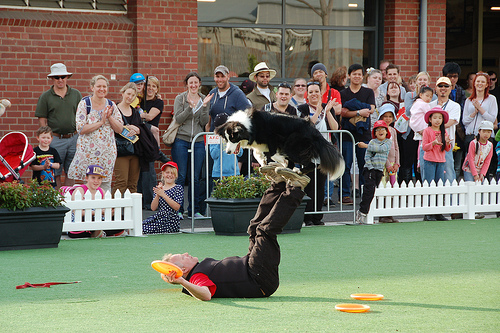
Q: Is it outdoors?
A: Yes, it is outdoors.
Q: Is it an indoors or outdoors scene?
A: It is outdoors.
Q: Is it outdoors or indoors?
A: It is outdoors.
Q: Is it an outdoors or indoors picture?
A: It is outdoors.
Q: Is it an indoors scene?
A: No, it is outdoors.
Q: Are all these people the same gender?
A: No, they are both male and female.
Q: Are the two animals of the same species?
A: Yes, all the animals are dogs.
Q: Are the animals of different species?
A: No, all the animals are dogs.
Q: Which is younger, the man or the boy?
A: The boy is younger than the man.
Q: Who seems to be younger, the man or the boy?
A: The boy is younger than the man.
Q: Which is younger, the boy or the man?
A: The boy is younger than the man.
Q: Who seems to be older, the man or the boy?
A: The man is older than the boy.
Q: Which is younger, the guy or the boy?
A: The boy is younger than the guy.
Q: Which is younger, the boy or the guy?
A: The boy is younger than the guy.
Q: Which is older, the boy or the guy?
A: The guy is older than the boy.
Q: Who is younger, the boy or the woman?
A: The boy is younger than the woman.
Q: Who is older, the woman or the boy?
A: The woman is older than the boy.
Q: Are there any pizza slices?
A: No, there are no pizza slices.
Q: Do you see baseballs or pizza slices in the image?
A: No, there are no pizza slices or baseballs.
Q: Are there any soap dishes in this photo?
A: No, there are no soap dishes.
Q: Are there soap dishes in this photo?
A: No, there are no soap dishes.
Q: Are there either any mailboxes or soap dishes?
A: No, there are no soap dishes or mailboxes.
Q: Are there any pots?
A: Yes, there is a pot.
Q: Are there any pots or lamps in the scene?
A: Yes, there is a pot.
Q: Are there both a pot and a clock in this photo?
A: No, there is a pot but no clocks.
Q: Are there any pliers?
A: No, there are no pliers.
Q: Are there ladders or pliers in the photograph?
A: No, there are no pliers or ladders.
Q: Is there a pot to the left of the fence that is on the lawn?
A: Yes, there is a pot to the left of the fence.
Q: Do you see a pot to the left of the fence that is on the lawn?
A: Yes, there is a pot to the left of the fence.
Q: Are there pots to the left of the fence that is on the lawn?
A: Yes, there is a pot to the left of the fence.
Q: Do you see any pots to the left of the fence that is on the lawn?
A: Yes, there is a pot to the left of the fence.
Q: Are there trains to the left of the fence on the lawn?
A: No, there is a pot to the left of the fence.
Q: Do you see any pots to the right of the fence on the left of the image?
A: Yes, there is a pot to the right of the fence.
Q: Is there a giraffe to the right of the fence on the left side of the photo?
A: No, there is a pot to the right of the fence.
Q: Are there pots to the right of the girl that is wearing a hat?
A: Yes, there is a pot to the right of the girl.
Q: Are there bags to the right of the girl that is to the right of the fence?
A: No, there is a pot to the right of the girl.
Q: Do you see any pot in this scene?
A: Yes, there is a pot.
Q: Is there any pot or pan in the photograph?
A: Yes, there is a pot.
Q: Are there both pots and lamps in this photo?
A: No, there is a pot but no lamps.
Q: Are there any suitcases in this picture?
A: No, there are no suitcases.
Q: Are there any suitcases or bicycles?
A: No, there are no suitcases or bicycles.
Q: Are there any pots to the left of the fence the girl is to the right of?
A: Yes, there is a pot to the left of the fence.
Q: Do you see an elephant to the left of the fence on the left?
A: No, there is a pot to the left of the fence.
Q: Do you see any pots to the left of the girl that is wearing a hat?
A: Yes, there is a pot to the left of the girl.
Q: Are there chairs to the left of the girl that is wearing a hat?
A: No, there is a pot to the left of the girl.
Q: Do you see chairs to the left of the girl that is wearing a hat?
A: No, there is a pot to the left of the girl.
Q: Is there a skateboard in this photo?
A: No, there are no skateboards.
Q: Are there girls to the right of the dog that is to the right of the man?
A: Yes, there is a girl to the right of the dog.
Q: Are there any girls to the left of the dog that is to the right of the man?
A: No, the girl is to the right of the dog.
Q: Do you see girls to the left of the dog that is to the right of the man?
A: No, the girl is to the right of the dog.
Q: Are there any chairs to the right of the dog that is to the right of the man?
A: No, there is a girl to the right of the dog.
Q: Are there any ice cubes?
A: No, there are no ice cubes.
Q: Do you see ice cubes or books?
A: No, there are no ice cubes or books.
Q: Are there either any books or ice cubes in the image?
A: No, there are no ice cubes or books.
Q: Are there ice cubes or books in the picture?
A: No, there are no ice cubes or books.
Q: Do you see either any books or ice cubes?
A: No, there are no ice cubes or books.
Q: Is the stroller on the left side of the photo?
A: Yes, the stroller is on the left of the image.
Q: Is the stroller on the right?
A: No, the stroller is on the left of the image.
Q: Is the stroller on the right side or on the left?
A: The stroller is on the left of the image.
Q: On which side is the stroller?
A: The stroller is on the left of the image.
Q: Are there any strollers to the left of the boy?
A: Yes, there is a stroller to the left of the boy.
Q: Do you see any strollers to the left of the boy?
A: Yes, there is a stroller to the left of the boy.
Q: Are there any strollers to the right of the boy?
A: No, the stroller is to the left of the boy.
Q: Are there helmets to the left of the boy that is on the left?
A: No, there is a stroller to the left of the boy.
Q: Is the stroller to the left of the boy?
A: Yes, the stroller is to the left of the boy.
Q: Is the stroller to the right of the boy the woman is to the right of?
A: No, the stroller is to the left of the boy.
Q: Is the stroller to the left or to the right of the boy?
A: The stroller is to the left of the boy.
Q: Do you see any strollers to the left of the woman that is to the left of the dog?
A: Yes, there is a stroller to the left of the woman.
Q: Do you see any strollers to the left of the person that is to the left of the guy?
A: Yes, there is a stroller to the left of the woman.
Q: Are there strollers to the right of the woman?
A: No, the stroller is to the left of the woman.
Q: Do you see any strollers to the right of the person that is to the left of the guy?
A: No, the stroller is to the left of the woman.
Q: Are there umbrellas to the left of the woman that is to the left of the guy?
A: No, there is a stroller to the left of the woman.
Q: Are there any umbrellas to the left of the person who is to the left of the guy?
A: No, there is a stroller to the left of the woman.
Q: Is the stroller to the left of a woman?
A: Yes, the stroller is to the left of a woman.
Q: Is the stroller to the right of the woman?
A: No, the stroller is to the left of the woman.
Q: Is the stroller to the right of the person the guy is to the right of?
A: No, the stroller is to the left of the woman.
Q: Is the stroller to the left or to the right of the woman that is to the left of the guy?
A: The stroller is to the left of the woman.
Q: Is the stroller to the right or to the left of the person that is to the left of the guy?
A: The stroller is to the left of the woman.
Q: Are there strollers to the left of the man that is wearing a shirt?
A: Yes, there is a stroller to the left of the man.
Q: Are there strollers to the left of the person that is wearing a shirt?
A: Yes, there is a stroller to the left of the man.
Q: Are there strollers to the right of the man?
A: No, the stroller is to the left of the man.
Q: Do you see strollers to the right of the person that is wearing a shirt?
A: No, the stroller is to the left of the man.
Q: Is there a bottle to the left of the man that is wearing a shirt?
A: No, there is a stroller to the left of the man.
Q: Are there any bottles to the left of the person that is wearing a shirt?
A: No, there is a stroller to the left of the man.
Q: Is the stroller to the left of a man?
A: Yes, the stroller is to the left of a man.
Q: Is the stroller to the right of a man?
A: No, the stroller is to the left of a man.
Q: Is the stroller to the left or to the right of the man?
A: The stroller is to the left of the man.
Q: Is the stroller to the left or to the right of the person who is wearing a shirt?
A: The stroller is to the left of the man.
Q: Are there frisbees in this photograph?
A: Yes, there is a frisbee.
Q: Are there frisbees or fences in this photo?
A: Yes, there is a frisbee.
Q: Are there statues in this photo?
A: No, there are no statues.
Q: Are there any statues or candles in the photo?
A: No, there are no statues or candles.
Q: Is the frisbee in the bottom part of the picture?
A: Yes, the frisbee is in the bottom of the image.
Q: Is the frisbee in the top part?
A: No, the frisbee is in the bottom of the image.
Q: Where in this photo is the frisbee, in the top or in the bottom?
A: The frisbee is in the bottom of the image.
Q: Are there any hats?
A: Yes, there is a hat.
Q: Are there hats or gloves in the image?
A: Yes, there is a hat.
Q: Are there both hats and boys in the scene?
A: Yes, there are both a hat and a boy.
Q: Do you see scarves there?
A: No, there are no scarves.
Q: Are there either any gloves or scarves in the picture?
A: No, there are no scarves or gloves.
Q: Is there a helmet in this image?
A: No, there are no helmets.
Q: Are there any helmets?
A: No, there are no helmets.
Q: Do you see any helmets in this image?
A: No, there are no helmets.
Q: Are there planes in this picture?
A: No, there are no planes.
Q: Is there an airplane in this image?
A: No, there are no airplanes.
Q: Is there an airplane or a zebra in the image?
A: No, there are no airplanes or zebras.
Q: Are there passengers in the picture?
A: No, there are no passengers.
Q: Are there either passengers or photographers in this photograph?
A: No, there are no passengers or photographers.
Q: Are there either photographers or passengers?
A: No, there are no passengers or photographers.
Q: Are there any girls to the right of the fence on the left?
A: Yes, there is a girl to the right of the fence.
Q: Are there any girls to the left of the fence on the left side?
A: No, the girl is to the right of the fence.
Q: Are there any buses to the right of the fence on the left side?
A: No, there is a girl to the right of the fence.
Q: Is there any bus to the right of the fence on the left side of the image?
A: No, there is a girl to the right of the fence.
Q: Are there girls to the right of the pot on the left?
A: Yes, there is a girl to the right of the pot.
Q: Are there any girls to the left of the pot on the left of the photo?
A: No, the girl is to the right of the pot.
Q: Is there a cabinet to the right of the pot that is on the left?
A: No, there is a girl to the right of the pot.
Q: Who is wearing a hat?
A: The girl is wearing a hat.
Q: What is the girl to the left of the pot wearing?
A: The girl is wearing a hat.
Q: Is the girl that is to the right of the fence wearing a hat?
A: Yes, the girl is wearing a hat.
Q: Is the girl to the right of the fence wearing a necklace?
A: No, the girl is wearing a hat.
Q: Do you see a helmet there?
A: No, there are no helmets.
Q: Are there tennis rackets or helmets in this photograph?
A: No, there are no helmets or tennis rackets.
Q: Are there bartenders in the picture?
A: No, there are no bartenders.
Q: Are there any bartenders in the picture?
A: No, there are no bartenders.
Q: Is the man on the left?
A: Yes, the man is on the left of the image.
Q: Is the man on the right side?
A: No, the man is on the left of the image.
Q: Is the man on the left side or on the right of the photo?
A: The man is on the left of the image.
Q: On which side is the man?
A: The man is on the left of the image.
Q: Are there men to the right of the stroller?
A: Yes, there is a man to the right of the stroller.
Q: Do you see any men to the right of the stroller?
A: Yes, there is a man to the right of the stroller.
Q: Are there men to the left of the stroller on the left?
A: No, the man is to the right of the stroller.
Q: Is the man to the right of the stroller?
A: Yes, the man is to the right of the stroller.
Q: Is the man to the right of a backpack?
A: No, the man is to the right of the stroller.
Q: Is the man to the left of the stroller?
A: No, the man is to the right of the stroller.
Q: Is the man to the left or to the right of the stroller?
A: The man is to the right of the stroller.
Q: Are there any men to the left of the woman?
A: Yes, there is a man to the left of the woman.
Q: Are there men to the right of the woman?
A: No, the man is to the left of the woman.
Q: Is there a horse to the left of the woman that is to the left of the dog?
A: No, there is a man to the left of the woman.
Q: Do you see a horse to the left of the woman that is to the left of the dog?
A: No, there is a man to the left of the woman.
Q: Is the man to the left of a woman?
A: Yes, the man is to the left of a woman.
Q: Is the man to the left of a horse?
A: No, the man is to the left of a woman.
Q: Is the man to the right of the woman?
A: No, the man is to the left of the woman.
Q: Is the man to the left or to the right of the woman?
A: The man is to the left of the woman.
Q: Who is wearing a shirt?
A: The man is wearing a shirt.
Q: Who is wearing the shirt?
A: The man is wearing a shirt.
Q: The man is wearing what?
A: The man is wearing a shirt.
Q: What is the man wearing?
A: The man is wearing a shirt.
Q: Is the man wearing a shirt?
A: Yes, the man is wearing a shirt.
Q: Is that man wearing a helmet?
A: No, the man is wearing a shirt.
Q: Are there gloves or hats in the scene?
A: Yes, there is a hat.